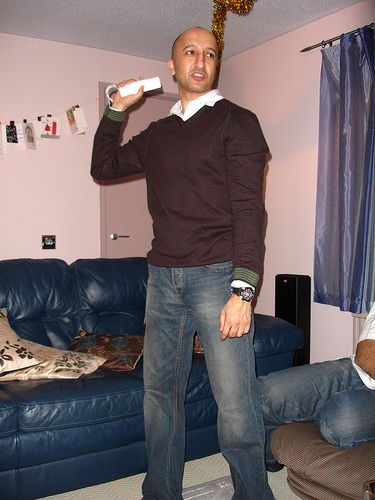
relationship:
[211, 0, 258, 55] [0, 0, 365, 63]
christmas tinsel hanging from ceiling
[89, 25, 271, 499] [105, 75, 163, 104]
man holding wii controller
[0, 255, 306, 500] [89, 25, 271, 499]
couch behind man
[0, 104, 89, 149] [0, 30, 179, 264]
christmas cards taped to wall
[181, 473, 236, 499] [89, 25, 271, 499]
rug under man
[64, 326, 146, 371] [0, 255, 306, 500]
pillow on couch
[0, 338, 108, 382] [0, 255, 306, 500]
pillow on couch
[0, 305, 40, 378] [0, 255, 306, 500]
pillow on couch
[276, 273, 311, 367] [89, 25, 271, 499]
speaker behind man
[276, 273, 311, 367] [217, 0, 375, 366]
speaker on wall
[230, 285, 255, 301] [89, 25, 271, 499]
watch on man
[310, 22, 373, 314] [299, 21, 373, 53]
curtains on rod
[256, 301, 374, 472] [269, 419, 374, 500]
person sitting in chair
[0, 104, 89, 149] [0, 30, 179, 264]
christmas cards hung in front of wall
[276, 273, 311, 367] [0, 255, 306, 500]
speaker to right of couch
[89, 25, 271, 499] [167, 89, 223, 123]
man wearing shirt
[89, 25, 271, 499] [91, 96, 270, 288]
man wearing shirt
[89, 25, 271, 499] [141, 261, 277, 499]
man wearing jeans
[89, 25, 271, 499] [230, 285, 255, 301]
man wearing watch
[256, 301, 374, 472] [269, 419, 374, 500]
man sitting on chair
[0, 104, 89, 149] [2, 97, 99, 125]
christmas cards hanging on string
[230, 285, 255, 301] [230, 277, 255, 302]
watch on wrist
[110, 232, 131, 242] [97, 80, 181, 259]
handle of door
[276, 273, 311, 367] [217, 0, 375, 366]
speaker against wall